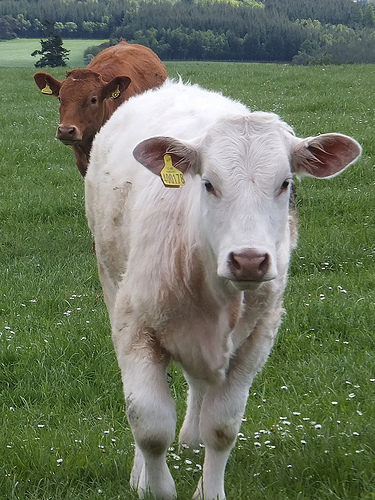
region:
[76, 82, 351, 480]
white cow in front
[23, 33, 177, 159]
brown cow in back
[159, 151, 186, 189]
yellow tag in cow's ear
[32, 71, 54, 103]
yellow tag in cow's ear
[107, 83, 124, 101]
tag in cow's ear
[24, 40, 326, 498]
cows standing on pasture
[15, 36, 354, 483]
pasture for cows to graze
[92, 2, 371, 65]
bushes and trees behind cows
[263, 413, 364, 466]
wild plants on pasture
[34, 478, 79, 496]
green grass on pasture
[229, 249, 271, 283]
nose on a white cow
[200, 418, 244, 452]
left knee with a black spot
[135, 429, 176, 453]
right knee with a black spot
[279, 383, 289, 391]
a little white flower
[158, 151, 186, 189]
a gold tag on the cow's ear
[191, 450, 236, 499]
lower part of the cow's left leg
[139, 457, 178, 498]
lower part of the cow's right leg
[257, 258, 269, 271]
right nostril on the cow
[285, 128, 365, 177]
cow's left ear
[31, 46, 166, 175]
brown cow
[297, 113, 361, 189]
ear of the cow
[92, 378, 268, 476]
legs of the cow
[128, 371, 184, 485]
one leg of the animal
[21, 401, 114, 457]
green grass on the ground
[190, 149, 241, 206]
eye of the cow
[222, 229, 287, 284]
nose of the cow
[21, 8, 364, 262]
two cows in photo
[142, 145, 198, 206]
tag on the ear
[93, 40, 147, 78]
brown fur on cow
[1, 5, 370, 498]
a scene in a field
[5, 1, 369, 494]
a scene during the day time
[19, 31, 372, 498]
two animals walking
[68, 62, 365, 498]
a white cow looking at camera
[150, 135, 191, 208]
a yellow tag on ear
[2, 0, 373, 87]
a row of trees in the background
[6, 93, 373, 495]
white flowers in grass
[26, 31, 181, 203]
a brown cow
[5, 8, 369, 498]
a photo of a meadow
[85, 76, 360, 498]
a white cow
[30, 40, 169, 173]
a brown cow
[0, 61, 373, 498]
white flower in a grassy field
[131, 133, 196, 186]
a yellow tag in the cow's ear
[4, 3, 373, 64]
trees line the back of a field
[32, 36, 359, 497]
two cows with yellow tags in their ears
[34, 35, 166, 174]
a brown cow with a tag in each ear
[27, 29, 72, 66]
a single pine tree in the middle of the field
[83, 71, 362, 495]
cow looking toward the camera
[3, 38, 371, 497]
large field of green grass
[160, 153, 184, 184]
the tag is yellow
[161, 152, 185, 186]
the black numbers on the yellow tag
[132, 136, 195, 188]
the tag hanging from the ear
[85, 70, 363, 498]
the cow is white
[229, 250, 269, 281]
the nose is pink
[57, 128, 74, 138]
the nose is brown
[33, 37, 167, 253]
the cow is brown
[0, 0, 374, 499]
the cows are standing on the grass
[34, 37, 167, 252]
the ear tags hanging from the cow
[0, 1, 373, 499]
the trees behind the cows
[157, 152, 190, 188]
A yellow tag on the white cow's ear.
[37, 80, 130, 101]
Yellow tags on both ears of the brown cow.